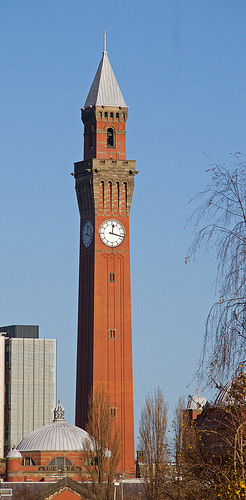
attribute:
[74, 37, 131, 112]
roof — grey, silver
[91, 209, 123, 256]
clock — white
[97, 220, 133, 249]
tower — grey, tall, red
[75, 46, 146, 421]
building — tall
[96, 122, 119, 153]
window — large, black, arched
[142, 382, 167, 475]
tree — green, brown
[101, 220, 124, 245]
time — 12:17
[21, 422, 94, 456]
dome — gray, tall, circular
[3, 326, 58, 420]
building — tall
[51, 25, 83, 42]
sky — blue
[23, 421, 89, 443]
dome — gray